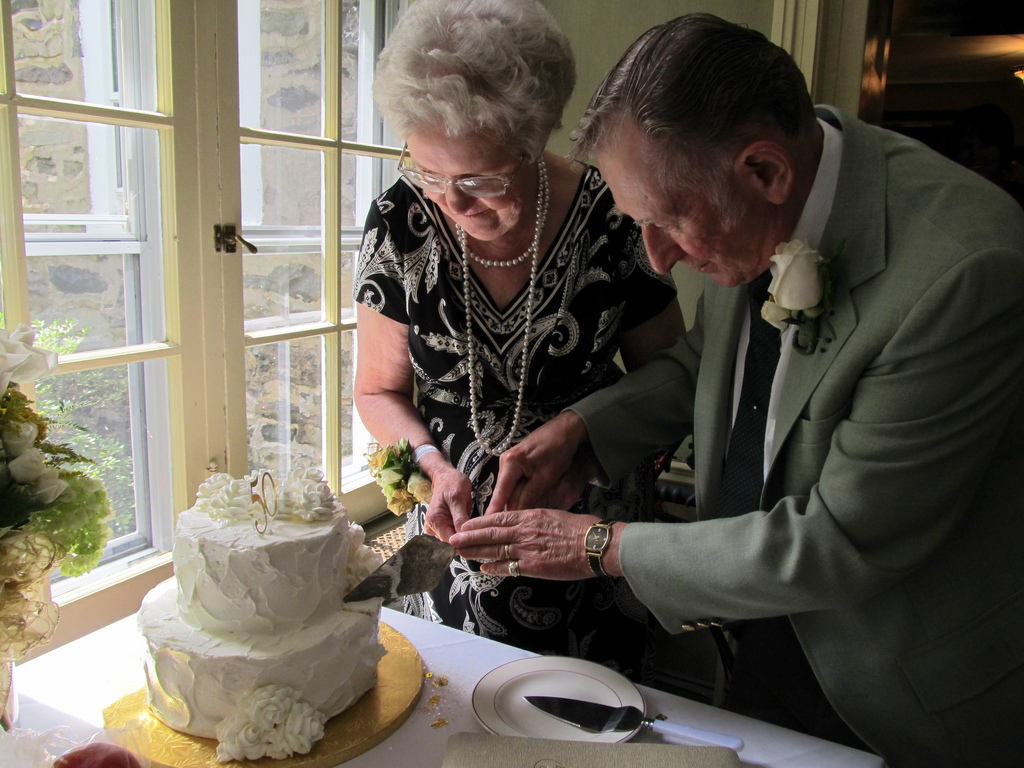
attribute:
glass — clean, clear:
[21, 0, 117, 219]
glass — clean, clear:
[334, 12, 386, 146]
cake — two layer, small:
[130, 443, 452, 735]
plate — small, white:
[474, 637, 669, 741]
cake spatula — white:
[472, 670, 732, 764]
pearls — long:
[407, 147, 576, 487]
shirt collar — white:
[785, 108, 840, 377]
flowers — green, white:
[25, 361, 155, 692]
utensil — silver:
[335, 532, 459, 610]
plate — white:
[466, 655, 644, 748]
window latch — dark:
[211, 219, 255, 261]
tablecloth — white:
[51, 577, 877, 765]